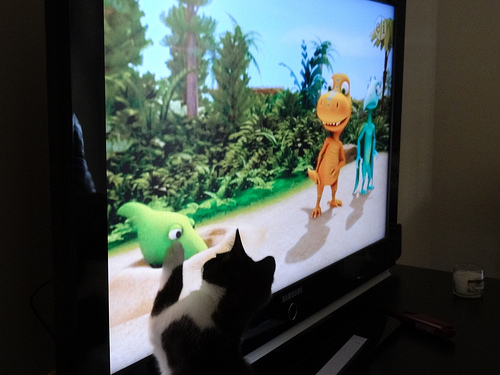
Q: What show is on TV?
A: Dinosaur Train.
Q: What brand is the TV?
A: Samsung.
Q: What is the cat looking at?
A: Dinosaur in a hole.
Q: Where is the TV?
A: TV stand.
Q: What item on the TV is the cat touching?
A: Eye of fish.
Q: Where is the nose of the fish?
A: Burrowing in sand.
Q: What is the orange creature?
A: Dinosaur.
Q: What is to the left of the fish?
A: Wooded area.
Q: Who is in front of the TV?
A: A black and white cat.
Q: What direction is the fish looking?
A: Down.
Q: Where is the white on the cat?
A: Under face and on chest.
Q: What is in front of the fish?
A: Sand.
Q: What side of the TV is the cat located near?
A: Left front.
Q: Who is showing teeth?
A: Orange dinosaur.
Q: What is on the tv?
A: Cartoon show.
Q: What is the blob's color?
A: Green.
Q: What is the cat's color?
A: Black and white.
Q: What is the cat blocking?
A: A tv screen.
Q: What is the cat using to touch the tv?
A: Paw.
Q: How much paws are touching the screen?
A: 1.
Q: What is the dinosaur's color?
A: Orange.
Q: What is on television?
A: A cartoon.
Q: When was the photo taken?
A: During the broadcast.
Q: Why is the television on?
A: To watch the program.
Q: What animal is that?
A: A cat.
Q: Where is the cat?
A: Near the television.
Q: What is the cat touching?
A: The television.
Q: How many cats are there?
A: One.